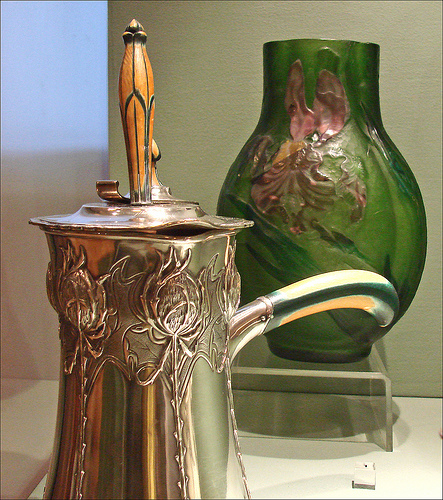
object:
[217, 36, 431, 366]
vase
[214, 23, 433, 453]
display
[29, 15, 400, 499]
canister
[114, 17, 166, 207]
handle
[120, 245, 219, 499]
foral design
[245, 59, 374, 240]
glass design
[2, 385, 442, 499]
display table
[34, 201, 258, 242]
top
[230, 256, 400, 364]
spout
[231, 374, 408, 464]
shadow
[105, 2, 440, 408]
wall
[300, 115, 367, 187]
light reflection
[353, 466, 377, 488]
clip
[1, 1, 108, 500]
wall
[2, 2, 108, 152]
blue color